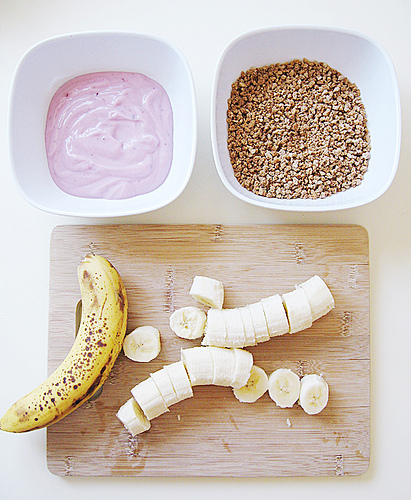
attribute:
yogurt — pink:
[43, 69, 174, 199]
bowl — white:
[204, 25, 398, 213]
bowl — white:
[4, 24, 195, 223]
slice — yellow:
[297, 273, 340, 317]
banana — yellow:
[291, 273, 337, 327]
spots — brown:
[2, 256, 125, 438]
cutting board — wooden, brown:
[44, 218, 375, 480]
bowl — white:
[8, 30, 197, 214]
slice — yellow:
[169, 304, 207, 339]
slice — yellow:
[204, 344, 236, 390]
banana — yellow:
[120, 273, 354, 437]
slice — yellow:
[114, 396, 149, 435]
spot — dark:
[98, 340, 105, 346]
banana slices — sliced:
[139, 245, 345, 440]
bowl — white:
[217, 29, 392, 202]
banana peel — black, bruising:
[3, 264, 85, 417]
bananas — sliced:
[98, 264, 366, 440]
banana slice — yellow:
[301, 374, 329, 415]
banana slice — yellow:
[267, 363, 302, 408]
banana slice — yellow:
[120, 324, 163, 362]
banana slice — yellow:
[167, 304, 205, 339]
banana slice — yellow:
[187, 272, 226, 307]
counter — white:
[3, 4, 409, 495]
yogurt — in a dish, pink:
[49, 79, 173, 192]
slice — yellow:
[297, 368, 333, 418]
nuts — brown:
[222, 52, 375, 202]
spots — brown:
[61, 329, 107, 384]